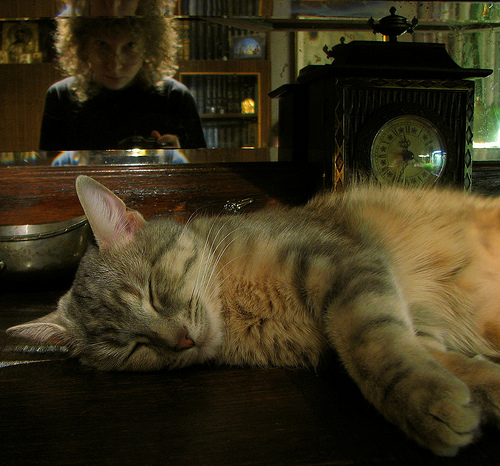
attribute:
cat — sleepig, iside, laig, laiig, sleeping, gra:
[10, 148, 496, 454]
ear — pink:
[64, 163, 152, 260]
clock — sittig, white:
[351, 96, 457, 202]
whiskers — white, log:
[173, 214, 251, 333]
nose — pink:
[164, 317, 201, 361]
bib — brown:
[207, 256, 335, 375]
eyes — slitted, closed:
[114, 255, 166, 370]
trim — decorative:
[348, 105, 456, 197]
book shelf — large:
[155, 3, 284, 161]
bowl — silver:
[1, 196, 113, 280]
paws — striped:
[411, 352, 496, 456]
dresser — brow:
[0, 155, 316, 302]